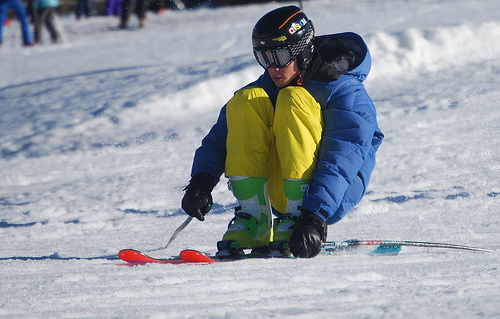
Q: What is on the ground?
A: Snow.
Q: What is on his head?
A: A helmet.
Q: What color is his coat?
A: Blue.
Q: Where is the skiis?
A: On the snow.